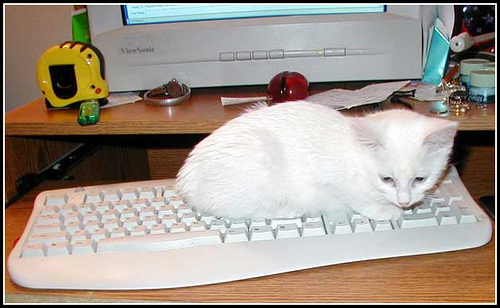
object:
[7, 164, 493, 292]
keyboard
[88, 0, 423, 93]
monitor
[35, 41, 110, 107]
toy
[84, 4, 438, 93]
computer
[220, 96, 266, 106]
object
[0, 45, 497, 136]
desk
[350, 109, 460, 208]
head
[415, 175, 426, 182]
eye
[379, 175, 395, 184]
eye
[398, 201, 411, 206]
nose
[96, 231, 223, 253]
space bar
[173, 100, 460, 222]
kitten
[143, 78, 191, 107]
watch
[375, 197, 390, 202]
whiskers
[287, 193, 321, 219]
stomach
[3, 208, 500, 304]
table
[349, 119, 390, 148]
ear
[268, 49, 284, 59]
knobs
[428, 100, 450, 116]
pencil sharpener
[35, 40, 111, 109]
paraphernalia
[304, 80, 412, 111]
papers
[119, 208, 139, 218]
keys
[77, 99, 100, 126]
cigarette lighter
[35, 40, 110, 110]
tape measure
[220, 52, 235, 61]
buttons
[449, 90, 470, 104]
wristwatch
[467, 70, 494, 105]
jars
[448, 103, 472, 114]
jewelery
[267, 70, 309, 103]
mouse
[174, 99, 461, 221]
cat